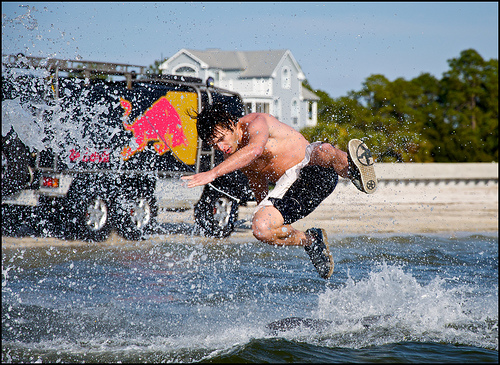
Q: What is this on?
A: Water.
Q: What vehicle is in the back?
A: Van.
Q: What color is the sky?
A: Blue.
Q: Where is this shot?
A: Pool.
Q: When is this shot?
A: Daytime.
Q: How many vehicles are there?
A: 1.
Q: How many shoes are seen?
A: 2.